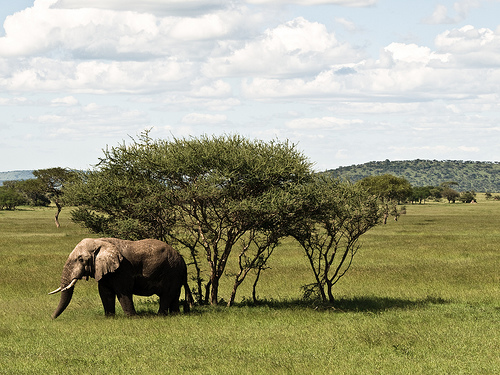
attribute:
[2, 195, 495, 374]
grass — green, thick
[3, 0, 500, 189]
sky — white, blue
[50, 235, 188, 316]
elephant — standing, alone, grey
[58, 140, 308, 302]
tree — large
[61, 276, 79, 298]
tusk — white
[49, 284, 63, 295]
tusk — white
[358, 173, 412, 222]
tree — small, scattered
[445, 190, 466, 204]
tree — small, scattered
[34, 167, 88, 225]
tree — small, scattered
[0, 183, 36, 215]
tree — small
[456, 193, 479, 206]
tree — small, scattered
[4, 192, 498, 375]
field — large, open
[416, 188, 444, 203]
tree — small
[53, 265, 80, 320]
nose — long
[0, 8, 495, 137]
clouds — puffy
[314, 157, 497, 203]
hill — covered